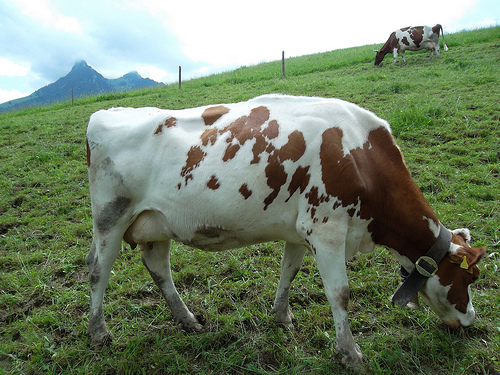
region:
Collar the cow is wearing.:
[391, 213, 445, 316]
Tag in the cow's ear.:
[451, 257, 485, 271]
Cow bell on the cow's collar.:
[382, 275, 434, 320]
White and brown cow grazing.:
[60, 96, 496, 342]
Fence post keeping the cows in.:
[170, 60, 190, 94]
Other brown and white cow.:
[353, 19, 462, 68]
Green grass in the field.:
[15, 281, 65, 351]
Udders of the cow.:
[110, 225, 177, 268]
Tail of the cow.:
[438, 24, 458, 61]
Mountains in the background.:
[38, 65, 162, 100]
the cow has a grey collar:
[386, 220, 461, 304]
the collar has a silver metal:
[408, 255, 448, 284]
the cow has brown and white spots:
[121, 127, 393, 249]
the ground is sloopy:
[13, 47, 494, 344]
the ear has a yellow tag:
[445, 256, 478, 274]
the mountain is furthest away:
[19, 57, 174, 114]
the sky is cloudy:
[18, 8, 375, 45]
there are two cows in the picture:
[3, 3, 499, 370]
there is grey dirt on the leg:
[78, 189, 157, 247]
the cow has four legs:
[64, 120, 475, 348]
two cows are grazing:
[83, 22, 488, 374]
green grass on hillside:
[0, 20, 499, 373]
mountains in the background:
[0, 59, 168, 112]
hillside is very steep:
[0, 22, 499, 374]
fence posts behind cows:
[68, 49, 289, 106]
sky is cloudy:
[0, 1, 499, 104]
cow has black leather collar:
[390, 224, 453, 310]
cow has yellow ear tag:
[459, 254, 469, 269]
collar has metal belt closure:
[416, 256, 438, 278]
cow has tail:
[438, 25, 448, 50]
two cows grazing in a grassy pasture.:
[72, 21, 478, 364]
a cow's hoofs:
[80, 310, 385, 370]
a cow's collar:
[387, 215, 448, 327]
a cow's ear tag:
[452, 252, 467, 272]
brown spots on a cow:
[180, 100, 315, 215]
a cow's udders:
[118, 216, 163, 252]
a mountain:
[0, 56, 170, 113]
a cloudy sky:
[3, 0, 358, 59]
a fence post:
[279, 49, 288, 79]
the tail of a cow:
[438, 25, 451, 52]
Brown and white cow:
[46, 80, 484, 362]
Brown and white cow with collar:
[55, 79, 478, 374]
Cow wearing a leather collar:
[46, 76, 494, 371]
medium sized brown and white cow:
[360, 14, 457, 76]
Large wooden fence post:
[173, 53, 187, 99]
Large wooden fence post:
[275, 43, 288, 81]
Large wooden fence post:
[62, 76, 79, 115]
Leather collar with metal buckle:
[379, 210, 463, 318]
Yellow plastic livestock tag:
[455, 244, 475, 275]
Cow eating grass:
[354, 0, 453, 82]